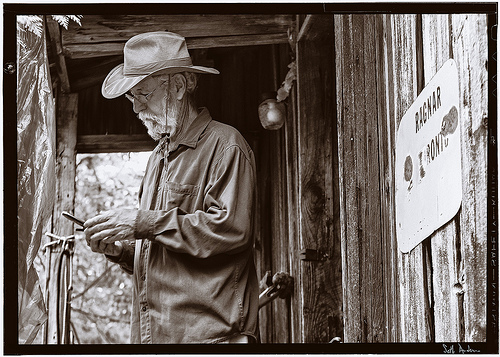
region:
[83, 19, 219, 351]
old man wearing a hat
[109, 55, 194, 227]
man wearing glasses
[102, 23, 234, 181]
a man with a white beard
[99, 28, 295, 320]
man wearing a cowboy hat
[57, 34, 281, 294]
man using a cellphone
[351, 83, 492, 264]
sign hanging on the wall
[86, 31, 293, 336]
man reading his cell phone screen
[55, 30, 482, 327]
man standing in front of a wooden structure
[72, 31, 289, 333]
old man with white hair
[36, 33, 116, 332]
knot tied in a rope on a wooden beam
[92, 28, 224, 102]
The old man's hat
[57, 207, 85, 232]
Cell phone the old man is holding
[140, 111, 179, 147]
The man's beard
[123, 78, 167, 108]
Glasses on the man's face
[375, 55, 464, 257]
Sign hanging on the wall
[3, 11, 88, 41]
Tree leaves above the man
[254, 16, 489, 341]
The wall behind the man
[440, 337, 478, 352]
The signature of the artist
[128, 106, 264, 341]
The man's shirt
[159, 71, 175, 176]
The string attached to the man's hat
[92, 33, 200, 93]
Man is wearing hat in his head.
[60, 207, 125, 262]
Man is holding mobile in his hand.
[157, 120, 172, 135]
Man beard is white in color.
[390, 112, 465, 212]
Board is white in color.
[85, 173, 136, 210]
Trees are seen behind the man.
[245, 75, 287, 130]
Lamp is hanging down from the wall.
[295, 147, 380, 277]
Walls are made of wood.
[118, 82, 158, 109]
Man is wearing eyeglass.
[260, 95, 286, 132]
Bulb is white color.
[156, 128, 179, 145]
Black color knob of hat.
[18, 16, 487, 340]
black and white photograph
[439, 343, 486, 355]
name of the photographer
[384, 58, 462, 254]
sign on the wooden house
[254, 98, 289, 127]
outdoor lighting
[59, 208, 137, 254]
hands holding a cellphone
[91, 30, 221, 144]
safari type hat on man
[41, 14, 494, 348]
old wooden type house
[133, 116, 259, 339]
button down shirt worn on man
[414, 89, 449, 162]
ragnar ronic written on sign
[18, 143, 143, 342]
outdoor outside of house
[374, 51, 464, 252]
white sign on cabin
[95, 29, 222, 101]
man is wearing a hat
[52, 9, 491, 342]
cabin is made of wood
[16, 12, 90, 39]
fern poking out from rooftop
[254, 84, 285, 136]
light on the outside of the cabin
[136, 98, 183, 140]
man has short white beard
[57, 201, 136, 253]
man is holding wood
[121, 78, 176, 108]
man is wearing glasses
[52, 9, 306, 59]
roof of porch has wood beams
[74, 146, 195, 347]
trees behind cabin